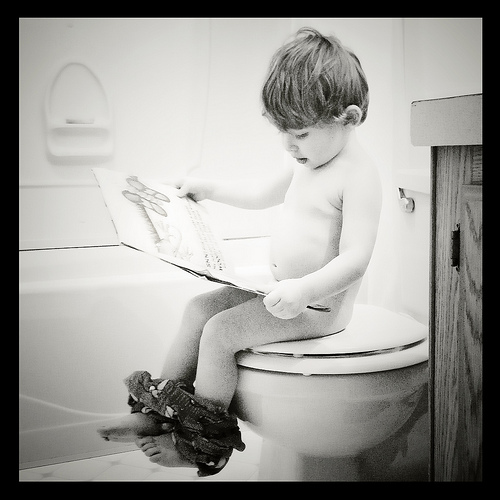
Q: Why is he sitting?
A: For the picture.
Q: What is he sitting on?
A: Toilet.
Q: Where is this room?
A: Bathroom.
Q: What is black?
A: Shorts.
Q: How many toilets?
A: One.